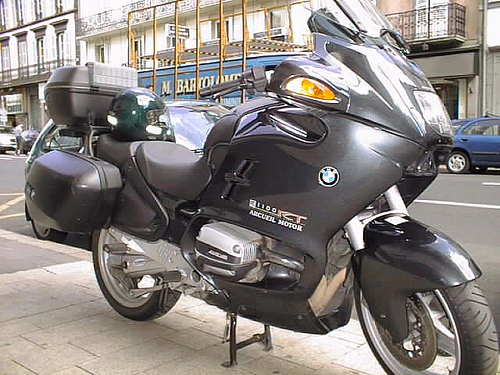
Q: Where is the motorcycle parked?
A: Sidewalk.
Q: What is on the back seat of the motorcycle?
A: Green helmet.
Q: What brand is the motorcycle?
A: BMW.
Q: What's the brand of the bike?
A: BMW.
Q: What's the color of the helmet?
A: Green.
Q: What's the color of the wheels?
A: Black.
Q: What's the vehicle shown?
A: Motorcycle.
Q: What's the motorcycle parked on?
A: Sidewalk.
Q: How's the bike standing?
A: Kickstand.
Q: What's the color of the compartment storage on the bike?
A: Black.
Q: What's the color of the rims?
A: Silver.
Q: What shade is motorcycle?
A: Gray.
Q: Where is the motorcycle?
A: Sidewalk.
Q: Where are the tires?
A: On motorcycle.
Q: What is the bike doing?
A: Parked.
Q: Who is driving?
A: No one.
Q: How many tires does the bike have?
A: 2.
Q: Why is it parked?
A: Wait for owner.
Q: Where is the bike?
A: On the sidewalk.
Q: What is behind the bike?
A: Building.